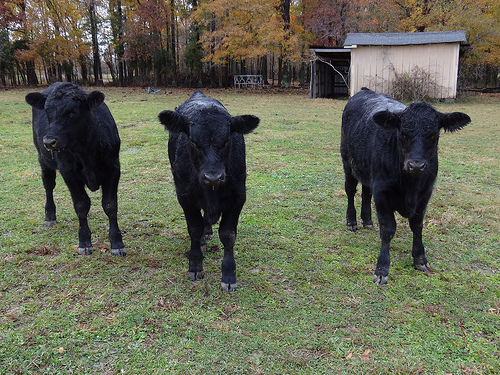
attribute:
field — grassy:
[115, 309, 450, 373]